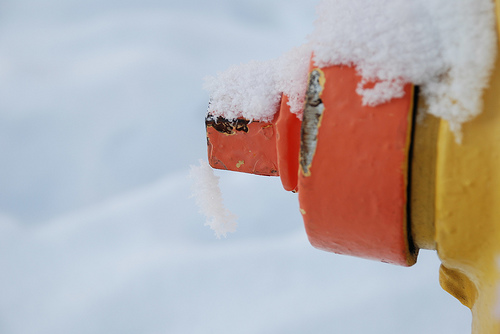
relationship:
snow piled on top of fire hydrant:
[7, 3, 497, 333] [199, 0, 500, 328]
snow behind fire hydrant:
[205, 0, 494, 149] [199, 0, 500, 328]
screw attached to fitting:
[205, 46, 302, 202] [297, 13, 475, 293]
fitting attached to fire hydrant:
[297, 14, 423, 294] [199, 0, 500, 328]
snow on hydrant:
[205, 0, 500, 138] [204, 8, 498, 319]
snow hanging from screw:
[193, 156, 229, 246] [194, 79, 315, 197]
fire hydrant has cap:
[199, 0, 500, 328] [196, 30, 302, 190]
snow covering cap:
[205, 0, 494, 149] [191, 36, 422, 262]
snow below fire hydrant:
[7, 3, 497, 333] [199, 0, 500, 328]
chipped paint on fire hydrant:
[302, 69, 328, 186] [199, 0, 500, 328]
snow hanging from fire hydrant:
[193, 156, 229, 246] [199, 0, 500, 328]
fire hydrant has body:
[199, 0, 500, 328] [414, 31, 496, 332]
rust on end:
[206, 112, 243, 138] [206, 64, 277, 180]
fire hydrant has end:
[199, 0, 500, 328] [206, 64, 277, 180]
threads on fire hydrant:
[407, 80, 431, 250] [199, 0, 500, 328]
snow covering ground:
[7, 3, 497, 333] [0, 3, 472, 333]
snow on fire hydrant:
[205, 0, 494, 149] [199, 0, 500, 328]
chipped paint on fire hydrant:
[204, 114, 251, 136] [199, 0, 500, 328]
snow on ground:
[80, 162, 223, 263] [0, 3, 472, 333]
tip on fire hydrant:
[205, 45, 315, 195] [199, 0, 500, 328]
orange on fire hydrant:
[205, 57, 415, 268] [199, 0, 500, 328]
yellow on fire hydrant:
[413, 31, 497, 332] [199, 0, 500, 328]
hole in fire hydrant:
[206, 118, 248, 134] [199, 0, 500, 328]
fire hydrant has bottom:
[199, 0, 500, 328] [425, 267, 494, 332]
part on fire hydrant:
[205, 45, 315, 195] [199, 25, 493, 332]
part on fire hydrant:
[303, 62, 409, 272] [199, 0, 500, 328]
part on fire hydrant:
[411, 54, 497, 332] [199, 25, 493, 332]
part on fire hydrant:
[434, 268, 497, 330] [199, 0, 500, 328]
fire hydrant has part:
[199, 25, 493, 332] [298, 71, 332, 181]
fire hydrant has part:
[199, 0, 500, 328] [202, 113, 257, 144]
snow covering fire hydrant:
[205, 0, 500, 138] [199, 0, 500, 328]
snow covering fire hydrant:
[205, 0, 494, 149] [199, 25, 493, 332]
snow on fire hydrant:
[205, 0, 500, 138] [206, 0, 497, 330]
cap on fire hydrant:
[202, 0, 415, 264] [199, 25, 493, 332]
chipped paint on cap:
[302, 69, 328, 186] [199, 0, 417, 265]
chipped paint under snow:
[204, 114, 251, 136] [201, 110, 252, 135]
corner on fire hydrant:
[435, 263, 478, 311] [199, 25, 493, 332]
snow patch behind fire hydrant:
[4, 0, 344, 214] [199, 25, 493, 332]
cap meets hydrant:
[199, 0, 417, 265] [409, 0, 497, 331]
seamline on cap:
[404, 70, 419, 260] [199, 0, 417, 265]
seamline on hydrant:
[404, 70, 419, 260] [409, 0, 497, 331]